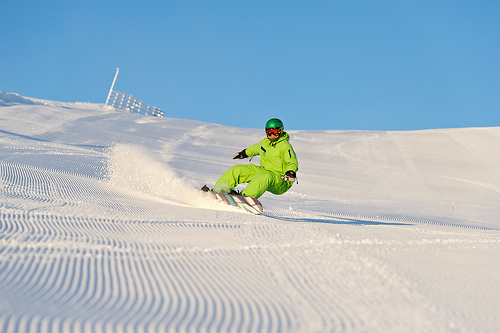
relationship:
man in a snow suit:
[193, 114, 311, 221] [218, 141, 297, 200]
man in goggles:
[209, 118, 298, 202] [262, 126, 284, 138]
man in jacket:
[209, 118, 298, 202] [238, 133, 301, 178]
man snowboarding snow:
[209, 118, 298, 202] [14, 107, 476, 331]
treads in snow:
[11, 223, 278, 330] [3, 90, 214, 332]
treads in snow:
[11, 223, 278, 330] [295, 122, 497, 332]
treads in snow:
[11, 223, 278, 330] [4, 206, 499, 329]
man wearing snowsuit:
[209, 118, 298, 202] [213, 135, 302, 196]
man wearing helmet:
[209, 118, 298, 202] [253, 105, 295, 142]